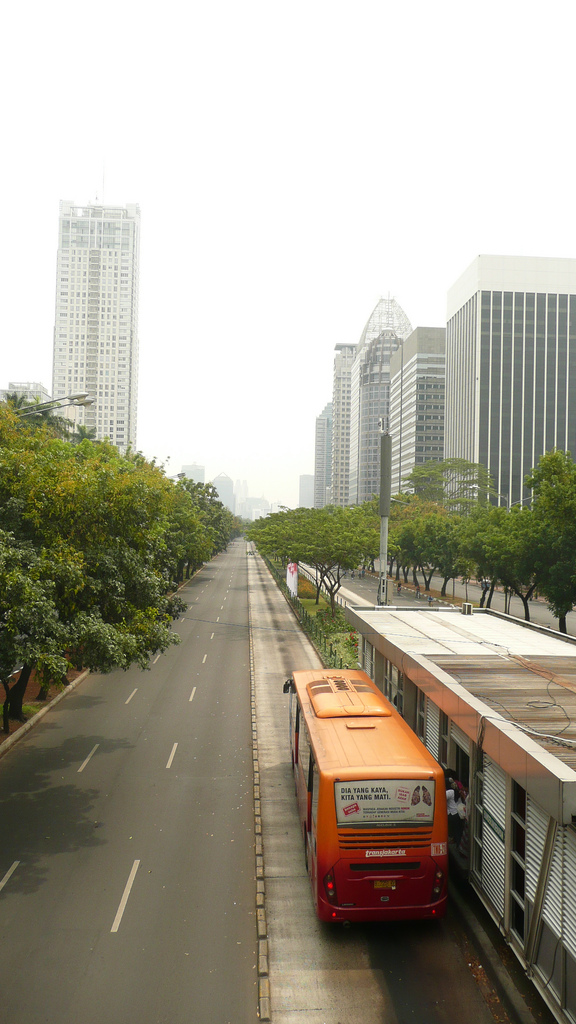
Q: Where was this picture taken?
A: In the center of a city.